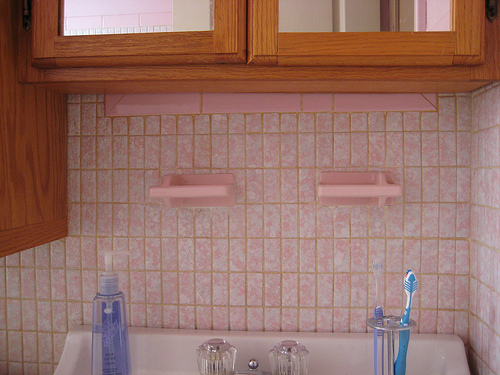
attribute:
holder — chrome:
[364, 309, 414, 370]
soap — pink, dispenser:
[143, 163, 226, 211]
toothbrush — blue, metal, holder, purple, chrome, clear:
[394, 268, 426, 314]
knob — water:
[198, 334, 259, 372]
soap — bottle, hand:
[93, 254, 154, 349]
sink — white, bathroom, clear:
[201, 291, 451, 375]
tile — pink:
[199, 127, 257, 156]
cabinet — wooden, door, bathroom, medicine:
[179, 25, 387, 123]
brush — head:
[391, 257, 454, 329]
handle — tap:
[279, 336, 307, 368]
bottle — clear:
[87, 300, 144, 360]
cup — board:
[10, 98, 111, 237]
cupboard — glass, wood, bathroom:
[93, 12, 303, 97]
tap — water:
[235, 344, 266, 374]